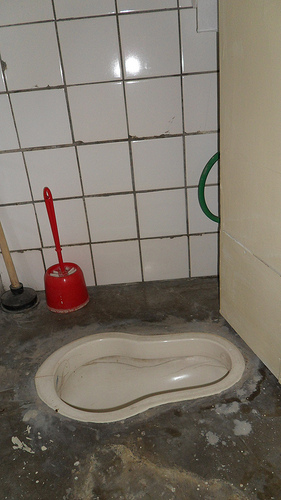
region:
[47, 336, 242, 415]
the toilet is white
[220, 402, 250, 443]
white spots are white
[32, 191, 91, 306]
the toiletbrush is white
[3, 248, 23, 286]
the handle is brown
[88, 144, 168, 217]
the tiles are white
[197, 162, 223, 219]
the pipe is blue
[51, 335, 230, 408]
the toilet is clean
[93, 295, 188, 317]
water is on the floor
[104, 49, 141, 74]
light reflection is on the wall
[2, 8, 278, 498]
the scene is indoors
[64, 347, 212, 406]
this is a toilet sink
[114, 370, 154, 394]
the sink is white in color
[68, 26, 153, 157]
this is the wall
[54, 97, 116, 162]
the wall is white in color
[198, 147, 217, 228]
this is a pipe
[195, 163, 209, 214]
the pipe is green in color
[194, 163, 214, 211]
the pipe is made of plastic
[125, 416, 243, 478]
this is the floor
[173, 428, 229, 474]
the floor is old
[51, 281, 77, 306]
this is a container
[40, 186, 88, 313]
the toilet brush is made of plastic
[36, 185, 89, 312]
the toilet brush is red in color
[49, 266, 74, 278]
the brush bristles are white in color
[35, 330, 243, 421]
the basin is made of ceramic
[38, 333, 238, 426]
the basin is white in color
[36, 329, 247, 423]
the basin is on the floor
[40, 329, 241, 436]
the basin is shiny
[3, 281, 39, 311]
the plunger is made of rubber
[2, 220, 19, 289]
the handle is made of wood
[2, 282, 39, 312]
the plunger is black in color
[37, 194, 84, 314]
the toilet brush is red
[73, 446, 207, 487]
the floor is grey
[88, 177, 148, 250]
tiles are on the wall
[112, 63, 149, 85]
light reflection is on the wall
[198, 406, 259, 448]
white stains are on the floor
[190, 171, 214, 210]
the pipe is blue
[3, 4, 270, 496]
the room is a toilet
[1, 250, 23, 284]
the handle is wooden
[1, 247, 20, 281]
the handel is brown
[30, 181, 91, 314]
a red toilet brush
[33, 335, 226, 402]
A stained toilet plate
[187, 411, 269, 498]
A stained toilet floor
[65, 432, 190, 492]
A stained toilet floor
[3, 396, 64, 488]
A stained toilet floor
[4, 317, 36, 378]
A stained toilet floor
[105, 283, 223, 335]
A stained toilet floor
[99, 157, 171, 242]
A white tile wall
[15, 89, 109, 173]
A white tile wall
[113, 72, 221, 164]
A white tile wall